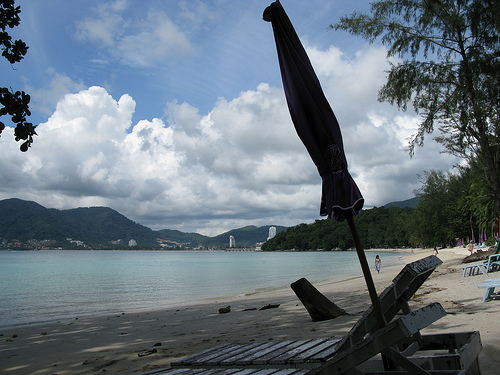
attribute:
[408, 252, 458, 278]
handle — pictured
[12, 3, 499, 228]
sky — blue, white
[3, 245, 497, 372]
sand — brown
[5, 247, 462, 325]
water — white, blue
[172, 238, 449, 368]
chair — wooden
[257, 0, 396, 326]
umbrella — folded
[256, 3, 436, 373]
umbrella — tall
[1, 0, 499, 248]
leaves — green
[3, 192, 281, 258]
mountain — large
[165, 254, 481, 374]
chair — wood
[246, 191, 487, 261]
trees — green